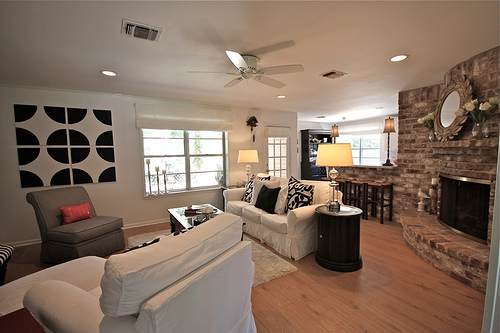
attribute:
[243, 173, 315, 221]
pillows — black , white 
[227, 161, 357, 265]
sofa — white 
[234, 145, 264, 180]
silver lamp — clear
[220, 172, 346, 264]
couch — white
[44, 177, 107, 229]
pillow — Red 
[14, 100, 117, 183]
tpicture — black, white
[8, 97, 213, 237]
art — Black , white 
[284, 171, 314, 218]
pillow — white, black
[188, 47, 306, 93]
ceiling fan — white 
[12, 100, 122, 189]
picture — white, black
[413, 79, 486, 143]
framed mirror — round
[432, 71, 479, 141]
mirror — round, decorative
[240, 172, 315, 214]
pillow — white , black 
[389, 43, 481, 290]
wall — brick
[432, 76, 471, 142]
mirror — brick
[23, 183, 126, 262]
lounge chair — grey